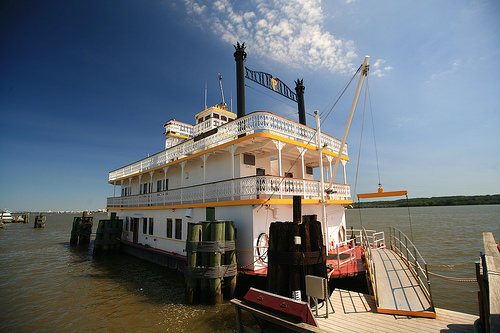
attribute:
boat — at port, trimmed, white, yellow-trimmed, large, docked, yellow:
[105, 41, 439, 319]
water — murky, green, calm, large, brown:
[0, 203, 499, 330]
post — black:
[230, 38, 249, 138]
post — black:
[292, 77, 307, 127]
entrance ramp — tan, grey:
[360, 246, 434, 315]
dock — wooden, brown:
[226, 277, 499, 332]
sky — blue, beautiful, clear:
[1, 1, 500, 212]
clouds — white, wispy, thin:
[178, 0, 389, 79]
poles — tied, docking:
[181, 217, 240, 304]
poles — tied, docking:
[92, 209, 124, 250]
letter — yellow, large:
[270, 77, 280, 93]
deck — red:
[250, 238, 376, 279]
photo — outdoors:
[0, 0, 500, 332]